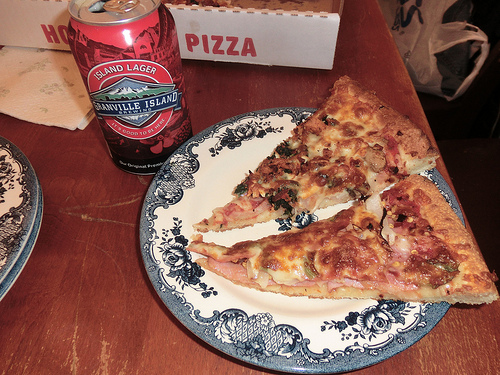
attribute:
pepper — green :
[301, 252, 320, 278]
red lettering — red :
[186, 19, 334, 77]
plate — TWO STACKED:
[0, 134, 40, 288]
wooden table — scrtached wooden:
[22, 119, 169, 348]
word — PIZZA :
[182, 31, 257, 58]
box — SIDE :
[0, 0, 346, 70]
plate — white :
[126, 84, 457, 374]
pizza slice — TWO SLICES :
[191, 69, 441, 231]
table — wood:
[193, 72, 304, 119]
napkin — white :
[1, 45, 96, 132]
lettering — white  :
[82, 59, 158, 82]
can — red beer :
[58, 4, 208, 185]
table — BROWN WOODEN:
[50, 255, 113, 333]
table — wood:
[50, 212, 125, 345]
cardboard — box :
[1, 0, 342, 69]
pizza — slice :
[183, 52, 498, 333]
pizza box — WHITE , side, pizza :
[0, 4, 347, 66]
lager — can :
[65, 0, 196, 178]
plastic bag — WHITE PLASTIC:
[381, 4, 490, 101]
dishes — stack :
[8, 150, 57, 285]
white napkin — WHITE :
[0, 43, 97, 131]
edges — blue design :
[135, 96, 484, 367]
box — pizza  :
[173, 8, 345, 73]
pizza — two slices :
[193, 80, 484, 325]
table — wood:
[4, 7, 479, 372]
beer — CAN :
[65, 9, 213, 172]